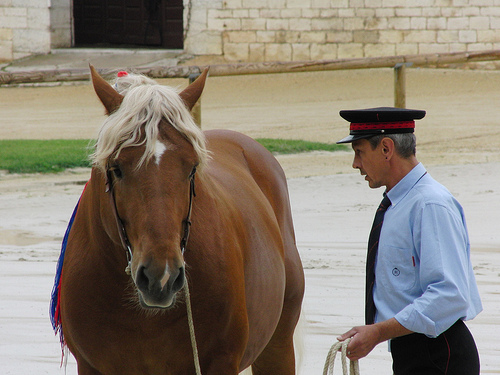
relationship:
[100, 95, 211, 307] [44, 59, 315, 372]
face of horse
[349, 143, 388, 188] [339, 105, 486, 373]
face of person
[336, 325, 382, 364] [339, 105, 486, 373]
hand of person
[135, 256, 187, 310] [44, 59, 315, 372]
nose of horse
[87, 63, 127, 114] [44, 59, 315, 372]
ear of horse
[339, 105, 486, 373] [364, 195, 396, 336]
person wearing tie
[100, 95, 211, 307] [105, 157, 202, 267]
face has bridle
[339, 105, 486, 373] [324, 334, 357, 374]
man holding rope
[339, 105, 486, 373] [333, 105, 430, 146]
man wearing hat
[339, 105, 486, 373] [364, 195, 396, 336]
man wearing tie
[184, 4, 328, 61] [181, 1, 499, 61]
bricks on wall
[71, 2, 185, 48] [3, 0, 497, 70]
doorway on wall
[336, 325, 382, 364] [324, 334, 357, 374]
hand holding rope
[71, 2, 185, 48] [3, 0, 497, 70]
doorway in wall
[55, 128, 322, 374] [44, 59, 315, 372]
body of horse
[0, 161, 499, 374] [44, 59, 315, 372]
ground below horse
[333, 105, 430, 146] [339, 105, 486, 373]
hat on man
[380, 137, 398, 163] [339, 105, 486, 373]
ear of man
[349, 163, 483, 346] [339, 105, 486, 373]
shirt on man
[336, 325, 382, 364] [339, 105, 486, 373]
hand of man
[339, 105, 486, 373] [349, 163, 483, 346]
man in shirt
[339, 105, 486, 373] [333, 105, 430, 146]
man wearing cap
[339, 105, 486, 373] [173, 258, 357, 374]
man has rope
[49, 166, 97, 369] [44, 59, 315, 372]
blanket on horse